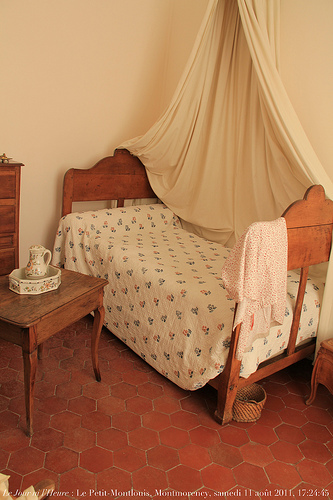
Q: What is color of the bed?
A: Brown.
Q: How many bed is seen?
A: One.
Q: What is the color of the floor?
A: Red.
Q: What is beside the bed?
A: Bedside table.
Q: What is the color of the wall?
A: White.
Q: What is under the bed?
A: Basket.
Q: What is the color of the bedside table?
A: Brown.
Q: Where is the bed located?
A: In a room.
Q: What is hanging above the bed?
A: A curtain.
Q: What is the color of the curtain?
A: White.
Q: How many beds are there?
A: One.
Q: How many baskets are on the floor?
A: One.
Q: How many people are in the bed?
A: Zero.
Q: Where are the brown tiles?
A: On the floor.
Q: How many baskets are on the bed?
A: Zero.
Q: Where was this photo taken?
A: In a bedroom.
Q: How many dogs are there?
A: Zero.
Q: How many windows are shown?
A: Zero.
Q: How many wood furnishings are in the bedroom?
A: 4.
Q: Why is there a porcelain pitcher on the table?
A: Tea.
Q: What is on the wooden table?
A: Porcelain pitcher set.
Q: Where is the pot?
A: Under the foot of bed.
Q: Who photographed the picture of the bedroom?
A: Teenage girl.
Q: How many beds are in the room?
A: 1.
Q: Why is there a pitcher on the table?
A: To hold hot liquids.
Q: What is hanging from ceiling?
A: Bed veil.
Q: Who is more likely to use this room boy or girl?
A: Girl.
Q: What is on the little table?
A: Pitcher and bowl.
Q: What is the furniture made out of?
A: Wood.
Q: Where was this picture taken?
A: Bedroom.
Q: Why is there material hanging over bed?
A: Privacy.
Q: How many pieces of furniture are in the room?
A: 4.